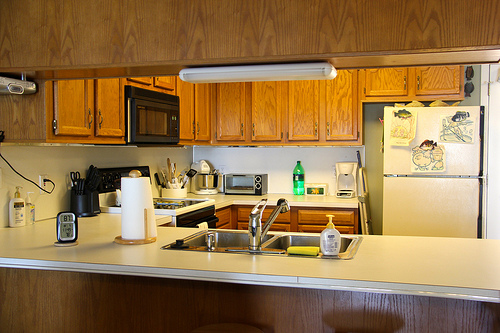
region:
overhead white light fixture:
[172, 54, 356, 89]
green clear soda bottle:
[282, 157, 315, 194]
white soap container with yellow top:
[315, 210, 352, 262]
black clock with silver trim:
[52, 212, 82, 244]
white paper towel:
[122, 176, 162, 231]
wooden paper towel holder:
[109, 169, 176, 236]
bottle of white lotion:
[3, 182, 38, 231]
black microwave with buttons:
[112, 82, 202, 147]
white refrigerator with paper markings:
[375, 103, 492, 240]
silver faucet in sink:
[240, 192, 293, 255]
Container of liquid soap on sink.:
[312, 206, 354, 266]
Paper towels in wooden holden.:
[105, 165, 166, 252]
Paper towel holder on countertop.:
[3, 217, 498, 304]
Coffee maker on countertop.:
[80, 152, 365, 209]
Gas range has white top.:
[78, 155, 220, 227]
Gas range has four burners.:
[85, 159, 215, 224]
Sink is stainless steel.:
[158, 203, 365, 275]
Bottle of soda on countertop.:
[283, 151, 309, 203]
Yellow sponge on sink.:
[280, 240, 325, 261]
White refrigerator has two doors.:
[364, 98, 495, 250]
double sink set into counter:
[145, 185, 377, 267]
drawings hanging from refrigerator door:
[380, 96, 485, 236]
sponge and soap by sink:
[277, 201, 348, 256]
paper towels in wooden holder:
[100, 160, 180, 250]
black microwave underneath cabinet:
[95, 80, 195, 150]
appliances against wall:
[185, 155, 281, 197]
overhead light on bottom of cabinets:
[160, 61, 347, 86]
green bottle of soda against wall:
[281, 150, 311, 200]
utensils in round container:
[150, 151, 205, 206]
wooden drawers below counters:
[215, 201, 366, 228]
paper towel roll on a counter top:
[105, 163, 167, 252]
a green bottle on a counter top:
[287, 157, 309, 201]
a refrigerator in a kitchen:
[374, 88, 495, 268]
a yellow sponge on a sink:
[278, 236, 323, 274]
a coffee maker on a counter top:
[329, 155, 360, 205]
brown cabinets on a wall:
[203, 60, 368, 155]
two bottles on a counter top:
[6, 181, 43, 233]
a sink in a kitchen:
[162, 195, 367, 265]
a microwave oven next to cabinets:
[117, 80, 197, 153]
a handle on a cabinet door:
[321, 116, 336, 144]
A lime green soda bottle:
[286, 158, 308, 193]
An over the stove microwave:
[116, 83, 188, 146]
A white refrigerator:
[376, 103, 480, 237]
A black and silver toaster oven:
[220, 167, 272, 196]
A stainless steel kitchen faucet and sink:
[162, 193, 365, 261]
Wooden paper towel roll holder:
[109, 166, 160, 246]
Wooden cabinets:
[0, 63, 473, 143]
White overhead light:
[173, 58, 345, 86]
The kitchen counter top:
[1, 182, 498, 328]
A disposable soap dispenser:
[314, 212, 349, 259]